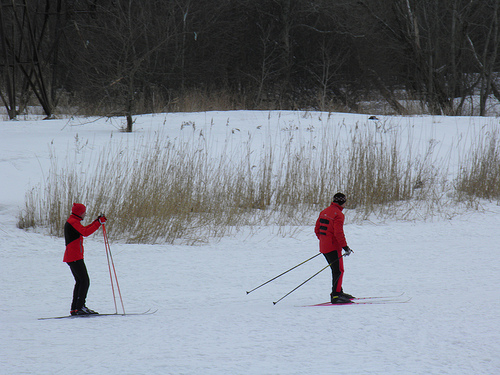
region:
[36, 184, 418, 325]
cross country skiers on the move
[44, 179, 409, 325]
cross country skiers wearing red and black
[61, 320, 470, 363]
flat snow covered ground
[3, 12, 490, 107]
leafless trees in the background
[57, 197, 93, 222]
red hat on persons head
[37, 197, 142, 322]
cross country skier with red poles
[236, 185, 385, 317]
cross country skier with black poles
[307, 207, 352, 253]
black stripes on red jacket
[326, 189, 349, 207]
black and tan hat on persons head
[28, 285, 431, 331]
cross country skis on the snow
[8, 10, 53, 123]
a tree in a distance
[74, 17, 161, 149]
a tree in a distance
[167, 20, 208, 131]
a tree in a distance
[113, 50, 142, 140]
a tree in a distance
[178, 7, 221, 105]
a tree in a distance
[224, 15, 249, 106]
a tree in a distance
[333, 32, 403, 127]
a tree in a distance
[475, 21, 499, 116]
a tree in a distance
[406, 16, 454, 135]
a tree in a distance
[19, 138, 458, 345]
two people are skiing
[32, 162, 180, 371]
a skier in red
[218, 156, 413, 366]
this skier has two poles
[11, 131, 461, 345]
both skiers are wearing red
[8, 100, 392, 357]
skiing past tall grass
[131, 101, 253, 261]
grass coming up from snow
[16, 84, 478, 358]
skiing is a winter sport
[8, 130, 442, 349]
these skiers are on a trail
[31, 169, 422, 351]
the snow is not fresh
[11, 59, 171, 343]
a skier in the wilderness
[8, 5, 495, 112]
dead trees with no leaves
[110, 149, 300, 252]
green grass growing in snow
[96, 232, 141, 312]
two ski poles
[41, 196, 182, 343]
Person in red and black suit skiing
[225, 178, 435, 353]
Man in red suit on skis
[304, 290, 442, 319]
two red skis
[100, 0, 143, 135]
large brown tree with no leaves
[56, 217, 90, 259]
red and black ski suit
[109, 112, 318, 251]
row of grass growing in snow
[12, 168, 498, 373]
two people skiing by snow covered grass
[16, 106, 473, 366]
Snow is covering the ground.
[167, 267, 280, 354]
The snow is white.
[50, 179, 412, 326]
Two people skiing.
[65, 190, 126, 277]
The person's coat is red.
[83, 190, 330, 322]
The people have poles in their hands.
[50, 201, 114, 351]
The person's pants are black.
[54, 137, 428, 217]
Tall grass growing out of the snow.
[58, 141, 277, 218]
The tall grass is brown.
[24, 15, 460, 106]
Trees in the background.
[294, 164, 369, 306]
The person's outfit is red.